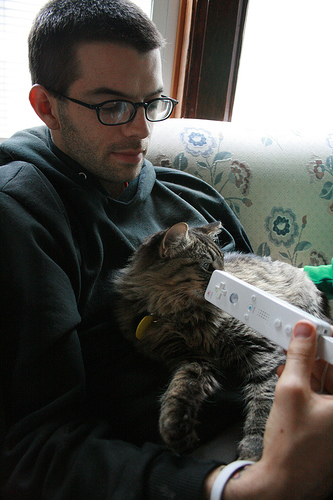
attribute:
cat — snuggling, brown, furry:
[107, 195, 286, 440]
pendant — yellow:
[127, 310, 157, 345]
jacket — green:
[4, 126, 159, 436]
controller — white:
[201, 276, 330, 362]